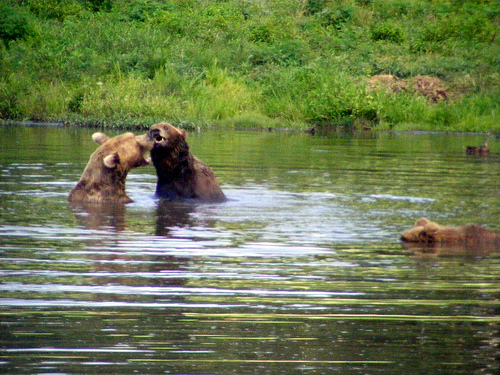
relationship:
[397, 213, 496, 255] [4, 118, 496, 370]
bear in water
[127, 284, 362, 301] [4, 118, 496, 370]
ripple in water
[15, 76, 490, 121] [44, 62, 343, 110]
ground has grass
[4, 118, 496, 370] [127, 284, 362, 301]
water has ripple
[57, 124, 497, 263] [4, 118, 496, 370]
bears are in water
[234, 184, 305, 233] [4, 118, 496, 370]
wave in water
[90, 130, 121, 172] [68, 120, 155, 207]
ears of left bear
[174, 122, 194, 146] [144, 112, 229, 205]
ear of right bear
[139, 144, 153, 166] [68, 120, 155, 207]
mouth of left bear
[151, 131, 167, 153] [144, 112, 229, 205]
mouth of right bear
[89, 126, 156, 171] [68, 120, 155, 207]
head of left bear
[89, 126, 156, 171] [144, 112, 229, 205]
head of right bear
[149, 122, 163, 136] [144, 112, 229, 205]
nose of right bear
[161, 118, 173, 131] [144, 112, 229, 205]
eye of right bear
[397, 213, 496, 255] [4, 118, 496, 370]
bear swimming in water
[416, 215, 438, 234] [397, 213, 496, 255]
ears of bear